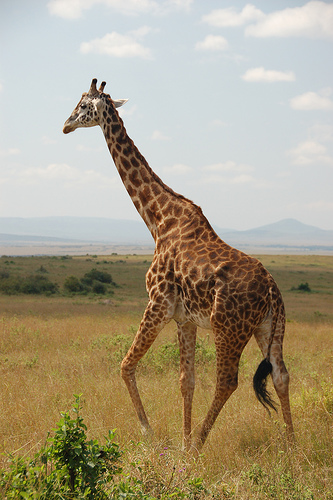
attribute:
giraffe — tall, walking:
[65, 78, 299, 453]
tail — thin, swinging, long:
[254, 290, 281, 416]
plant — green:
[30, 405, 115, 498]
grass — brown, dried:
[233, 440, 265, 483]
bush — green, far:
[298, 279, 313, 298]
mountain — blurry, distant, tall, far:
[238, 217, 328, 249]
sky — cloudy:
[132, 4, 332, 142]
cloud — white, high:
[243, 63, 295, 87]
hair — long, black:
[251, 358, 277, 418]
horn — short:
[90, 76, 100, 92]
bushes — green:
[5, 269, 117, 296]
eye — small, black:
[80, 103, 90, 111]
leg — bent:
[118, 281, 168, 454]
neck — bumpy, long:
[99, 125, 180, 233]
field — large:
[1, 244, 125, 492]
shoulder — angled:
[143, 252, 173, 297]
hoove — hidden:
[181, 456, 196, 465]